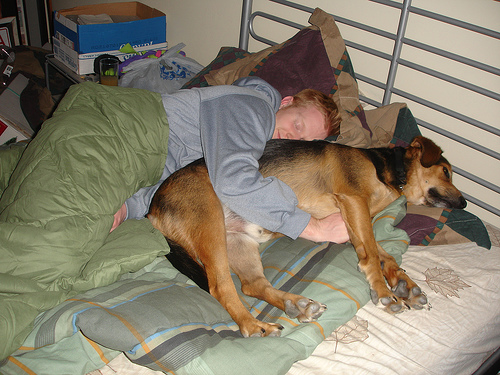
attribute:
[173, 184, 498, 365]
comforter — green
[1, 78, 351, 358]
man — asleep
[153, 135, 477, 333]
dog — sleeping, large, brown, black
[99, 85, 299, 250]
hoodie — grey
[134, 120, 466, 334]
dog — sleeping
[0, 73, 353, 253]
man — sleeping